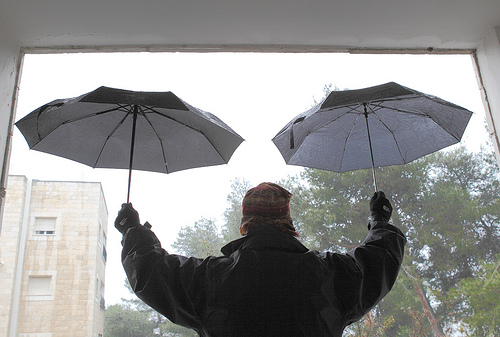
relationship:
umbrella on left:
[13, 86, 245, 226] [1, 9, 43, 337]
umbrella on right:
[270, 81, 473, 226] [468, 1, 499, 337]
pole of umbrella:
[125, 106, 139, 202] [13, 86, 245, 226]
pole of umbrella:
[362, 105, 378, 192] [270, 81, 473, 226]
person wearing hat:
[113, 181, 407, 336] [239, 182, 299, 238]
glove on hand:
[114, 202, 140, 233] [114, 202, 141, 234]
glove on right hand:
[368, 190, 394, 228] [367, 190, 393, 222]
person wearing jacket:
[113, 181, 407, 336] [119, 221, 406, 336]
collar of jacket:
[221, 233, 308, 257] [119, 221, 406, 336]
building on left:
[0, 174, 109, 335] [1, 9, 43, 337]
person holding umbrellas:
[113, 181, 407, 336] [13, 80, 474, 206]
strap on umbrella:
[289, 114, 306, 149] [270, 81, 473, 226]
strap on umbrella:
[34, 102, 61, 138] [13, 86, 245, 226]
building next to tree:
[0, 174, 109, 335] [105, 302, 153, 337]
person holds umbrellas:
[113, 181, 407, 336] [13, 80, 474, 206]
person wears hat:
[113, 181, 407, 336] [239, 182, 299, 238]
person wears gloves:
[113, 181, 407, 336] [114, 190, 393, 234]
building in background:
[0, 174, 109, 335] [11, 163, 500, 336]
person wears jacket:
[113, 181, 407, 336] [119, 221, 406, 336]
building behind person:
[0, 174, 109, 335] [113, 181, 407, 336]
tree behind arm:
[305, 170, 481, 335] [335, 223, 406, 328]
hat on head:
[239, 182, 299, 238] [239, 181, 295, 236]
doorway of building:
[0, 52, 499, 337] [1, 1, 499, 335]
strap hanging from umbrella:
[289, 114, 306, 149] [270, 81, 473, 226]